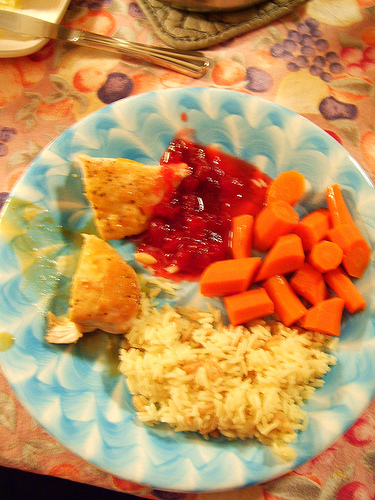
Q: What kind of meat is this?
A: Chicken.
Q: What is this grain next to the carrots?
A: Rice.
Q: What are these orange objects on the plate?
A: Carrots.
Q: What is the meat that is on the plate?
A: Chicken.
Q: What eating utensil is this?
A: Knife.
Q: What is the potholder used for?
A: To put pots on top of.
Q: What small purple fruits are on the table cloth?
A: Grapes.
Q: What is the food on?
A: Plate.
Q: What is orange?
A: Carrots.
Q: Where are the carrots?
A: On the plate.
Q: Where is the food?
A: On the plate.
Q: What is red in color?
A: The sauce.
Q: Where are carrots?
A: On a plate.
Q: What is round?
A: A plate.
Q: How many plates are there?
A: One.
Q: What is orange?
A: Carrots.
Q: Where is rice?
A: On plate.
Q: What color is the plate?
A: Blue and white.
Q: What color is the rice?
A: Light brown.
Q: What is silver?
A: Butter knife.